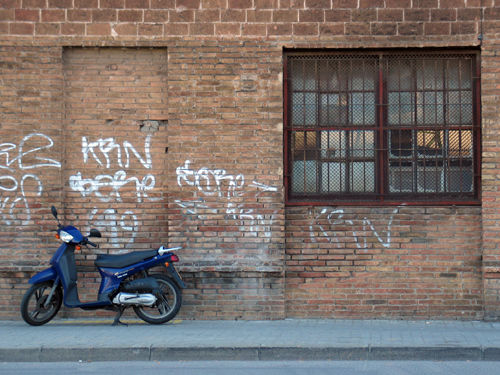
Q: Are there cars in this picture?
A: No, there are no cars.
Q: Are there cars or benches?
A: No, there are no cars or benches.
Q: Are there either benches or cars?
A: No, there are no cars or benches.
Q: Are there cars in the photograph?
A: No, there are no cars.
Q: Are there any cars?
A: No, there are no cars.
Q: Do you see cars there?
A: No, there are no cars.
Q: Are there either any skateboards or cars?
A: No, there are no cars or skateboards.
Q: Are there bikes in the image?
A: Yes, there is a bike.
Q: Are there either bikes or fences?
A: Yes, there is a bike.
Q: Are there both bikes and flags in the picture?
A: No, there is a bike but no flags.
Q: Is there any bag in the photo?
A: No, there are no bags.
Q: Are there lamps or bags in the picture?
A: No, there are no bags or lamps.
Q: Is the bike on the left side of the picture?
A: Yes, the bike is on the left of the image.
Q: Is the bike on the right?
A: No, the bike is on the left of the image.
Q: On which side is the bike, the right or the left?
A: The bike is on the left of the image.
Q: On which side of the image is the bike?
A: The bike is on the left of the image.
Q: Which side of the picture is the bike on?
A: The bike is on the left of the image.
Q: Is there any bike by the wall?
A: Yes, there is a bike by the wall.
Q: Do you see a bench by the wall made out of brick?
A: No, there is a bike by the wall.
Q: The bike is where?
A: The bike is on the pavement.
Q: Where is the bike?
A: The bike is on the pavement.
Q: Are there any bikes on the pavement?
A: Yes, there is a bike on the pavement.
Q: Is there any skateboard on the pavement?
A: No, there is a bike on the pavement.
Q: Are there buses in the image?
A: No, there are no buses.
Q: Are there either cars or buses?
A: No, there are no buses or cars.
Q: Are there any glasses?
A: No, there are no glasses.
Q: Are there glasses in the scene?
A: No, there are no glasses.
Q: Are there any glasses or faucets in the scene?
A: No, there are no glasses or faucets.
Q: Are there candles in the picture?
A: No, there are no candles.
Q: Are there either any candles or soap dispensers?
A: No, there are no candles or soap dispensers.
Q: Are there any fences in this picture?
A: No, there are no fences.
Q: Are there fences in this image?
A: No, there are no fences.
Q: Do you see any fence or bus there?
A: No, there are no fences or buses.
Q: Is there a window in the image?
A: Yes, there is a window.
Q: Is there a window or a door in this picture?
A: Yes, there is a window.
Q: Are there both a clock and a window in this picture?
A: No, there is a window but no clocks.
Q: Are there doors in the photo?
A: No, there are no doors.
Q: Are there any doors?
A: No, there are no doors.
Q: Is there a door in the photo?
A: No, there are no doors.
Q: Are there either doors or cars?
A: No, there are no doors or cars.